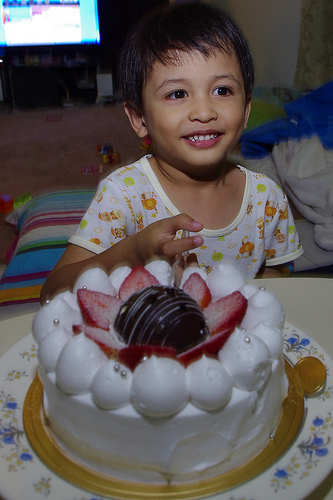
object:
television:
[1, 0, 98, 57]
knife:
[169, 226, 189, 288]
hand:
[131, 211, 202, 266]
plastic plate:
[25, 352, 325, 499]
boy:
[38, 2, 301, 304]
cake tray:
[0, 322, 333, 499]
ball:
[114, 283, 207, 353]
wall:
[32, 250, 288, 489]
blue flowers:
[20, 451, 30, 460]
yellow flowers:
[7, 367, 29, 383]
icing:
[31, 259, 288, 484]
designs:
[124, 174, 136, 186]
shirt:
[70, 152, 306, 284]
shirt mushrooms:
[239, 238, 255, 253]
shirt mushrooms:
[265, 200, 277, 216]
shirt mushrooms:
[278, 205, 289, 221]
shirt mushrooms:
[265, 245, 275, 259]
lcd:
[2, 2, 18, 16]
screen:
[0, 0, 99, 46]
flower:
[135, 212, 144, 231]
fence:
[282, 329, 310, 358]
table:
[0, 267, 332, 373]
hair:
[117, 0, 254, 115]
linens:
[242, 186, 299, 271]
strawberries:
[202, 291, 247, 331]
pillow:
[0, 189, 98, 308]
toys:
[81, 142, 118, 176]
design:
[140, 189, 156, 211]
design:
[265, 203, 277, 217]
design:
[239, 234, 253, 254]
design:
[99, 209, 123, 222]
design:
[112, 227, 125, 241]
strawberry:
[174, 326, 231, 366]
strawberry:
[118, 343, 148, 366]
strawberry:
[72, 323, 122, 359]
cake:
[23, 257, 326, 499]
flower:
[273, 467, 292, 484]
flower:
[298, 432, 329, 461]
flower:
[310, 413, 323, 427]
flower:
[5, 393, 20, 411]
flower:
[19, 449, 35, 462]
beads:
[121, 369, 125, 376]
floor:
[2, 92, 331, 306]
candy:
[117, 284, 208, 346]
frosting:
[30, 257, 289, 492]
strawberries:
[77, 288, 118, 330]